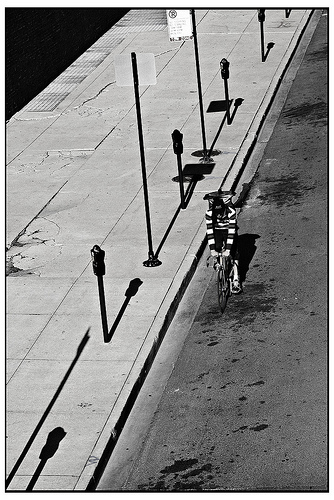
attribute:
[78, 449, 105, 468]
graffiti — painted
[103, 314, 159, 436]
curb — painted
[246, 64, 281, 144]
curb — painted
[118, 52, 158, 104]
lamp — street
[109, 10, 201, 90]
signs — black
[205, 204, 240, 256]
shirt — striped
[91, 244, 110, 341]
parking meter — small, black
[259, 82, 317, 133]
marks — black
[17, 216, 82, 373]
sidewalk — busted up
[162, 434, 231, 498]
stains — black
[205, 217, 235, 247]
striped — shirt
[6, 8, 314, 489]
sidewalk — raised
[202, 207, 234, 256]
shirt — striped